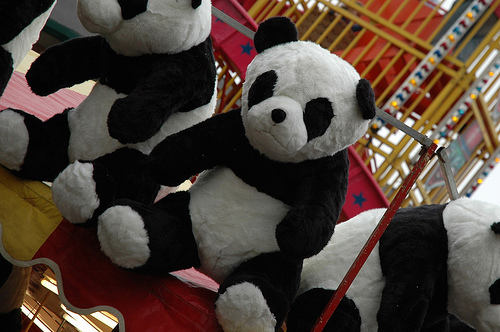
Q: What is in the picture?
A: Stuffed panda bears.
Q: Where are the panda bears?
A: In a basket.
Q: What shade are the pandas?
A: Black and white.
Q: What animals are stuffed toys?
A: Pandas.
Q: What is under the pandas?
A: Awning.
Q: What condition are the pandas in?
A: Stuffed.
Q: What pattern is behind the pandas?
A: Stars.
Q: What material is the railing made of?
A: Metal.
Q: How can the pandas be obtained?
A: Win.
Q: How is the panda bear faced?
A: Forward.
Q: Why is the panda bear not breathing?
A: It's stuffed.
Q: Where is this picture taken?
A: Carnival.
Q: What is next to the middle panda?
A: A red bar.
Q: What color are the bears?
A: Black and white.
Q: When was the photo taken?
A: Afternoon.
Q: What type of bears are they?
A: Panda.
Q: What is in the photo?
A: Stuffed animals.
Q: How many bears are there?
A: Three.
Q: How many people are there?
A: None.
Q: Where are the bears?
A: At a carnival.